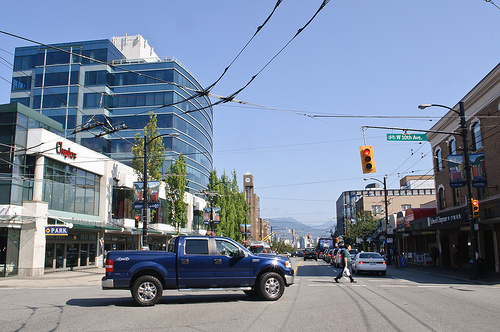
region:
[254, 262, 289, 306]
the front right wheel of a blue truck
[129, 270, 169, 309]
the rear right wheel of a blue truck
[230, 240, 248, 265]
the front right mirror of a blue truck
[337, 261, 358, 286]
a man carrying a white bag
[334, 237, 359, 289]
a man walking across a street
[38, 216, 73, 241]
a park sign on the side of a building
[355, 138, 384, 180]
a red light on a stoplight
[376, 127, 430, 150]
a green and white street sign on pole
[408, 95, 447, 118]
a street light above a street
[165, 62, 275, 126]
electric cables above a street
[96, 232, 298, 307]
blue truck on the road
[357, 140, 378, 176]
a traffic light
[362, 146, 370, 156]
a red light on traffic light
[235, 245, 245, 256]
a side of the mirror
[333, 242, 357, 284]
a guy crossing road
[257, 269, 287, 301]
front wheel of blue truck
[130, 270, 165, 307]
rear of the truck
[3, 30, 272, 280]
buildings in the background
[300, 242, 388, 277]
vehicles on the road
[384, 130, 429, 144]
street name of the road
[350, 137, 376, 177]
the traffic light is yellow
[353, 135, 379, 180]
traffic light is in red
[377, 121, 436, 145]
a green sign on pole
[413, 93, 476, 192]
a light on a pole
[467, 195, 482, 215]
traffic light hang from pole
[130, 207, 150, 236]
traffic light hang from pole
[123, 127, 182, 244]
light and traffic light hangs from pole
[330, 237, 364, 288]
man crossing the street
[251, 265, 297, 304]
front wheel of car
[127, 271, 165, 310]
back wheel of car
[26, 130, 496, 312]
this is a stree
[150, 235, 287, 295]
this is a truck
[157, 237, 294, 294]
it is blue in colour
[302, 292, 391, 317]
this is the road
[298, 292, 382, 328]
the road is tarmacked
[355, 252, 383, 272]
this is a car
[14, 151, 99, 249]
this is a building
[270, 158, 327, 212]
this is the sky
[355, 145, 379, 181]
these are the traffic lights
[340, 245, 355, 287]
the man is carrying a paper bag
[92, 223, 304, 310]
A pick up truck on a busy street